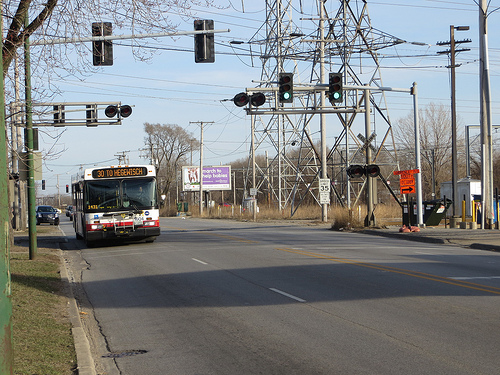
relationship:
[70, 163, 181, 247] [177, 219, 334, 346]
bus on road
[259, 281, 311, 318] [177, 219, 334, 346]
line on road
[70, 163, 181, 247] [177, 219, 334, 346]
bus in road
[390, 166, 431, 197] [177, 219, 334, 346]
sign near road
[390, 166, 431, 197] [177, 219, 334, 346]
sign by road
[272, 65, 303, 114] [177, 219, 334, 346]
light above road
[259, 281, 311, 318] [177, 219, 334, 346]
line in road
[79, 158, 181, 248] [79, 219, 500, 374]
bus driving down road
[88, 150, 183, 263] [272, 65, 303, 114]
bus has light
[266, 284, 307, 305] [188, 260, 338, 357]
line on road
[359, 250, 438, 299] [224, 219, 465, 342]
line on road